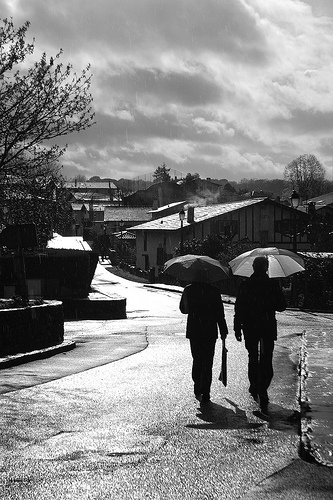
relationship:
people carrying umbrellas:
[177, 256, 232, 416] [173, 231, 322, 291]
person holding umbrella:
[177, 257, 230, 418] [158, 254, 230, 280]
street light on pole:
[174, 205, 189, 224] [178, 217, 186, 257]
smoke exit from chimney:
[186, 188, 219, 207] [183, 198, 193, 221]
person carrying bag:
[211, 235, 294, 352] [207, 326, 240, 380]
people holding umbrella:
[177, 256, 288, 406] [228, 246, 307, 291]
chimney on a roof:
[187, 205, 194, 222] [127, 194, 266, 233]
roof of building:
[122, 190, 314, 231] [126, 195, 309, 280]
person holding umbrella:
[231, 250, 290, 423] [225, 221, 311, 268]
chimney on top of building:
[187, 205, 194, 222] [128, 189, 311, 275]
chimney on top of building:
[151, 196, 158, 208] [126, 195, 309, 280]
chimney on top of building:
[73, 177, 79, 186] [50, 175, 117, 197]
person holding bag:
[179, 264, 222, 418] [216, 336, 230, 390]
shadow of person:
[184, 395, 265, 436] [177, 257, 230, 418]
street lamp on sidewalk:
[290, 187, 299, 304] [149, 281, 299, 310]